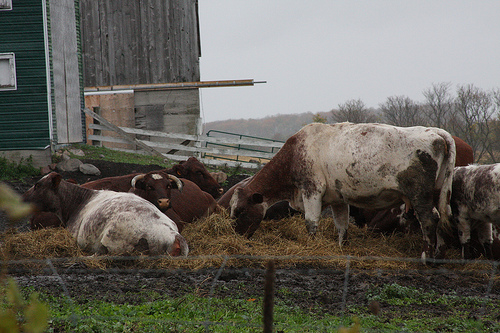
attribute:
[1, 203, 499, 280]
hay — piled, yellow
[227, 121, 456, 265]
cow — eating, brown, white, lying, standing, large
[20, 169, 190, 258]
cow — lying, lying down, white, brown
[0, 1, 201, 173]
barn — green, wooden, gray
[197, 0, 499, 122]
sky — grey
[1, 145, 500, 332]
ground — muddy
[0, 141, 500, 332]
grass — green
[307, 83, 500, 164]
trees — bare, gray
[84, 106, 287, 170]
fence — white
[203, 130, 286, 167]
gate — metal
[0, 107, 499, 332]
pen — muddy